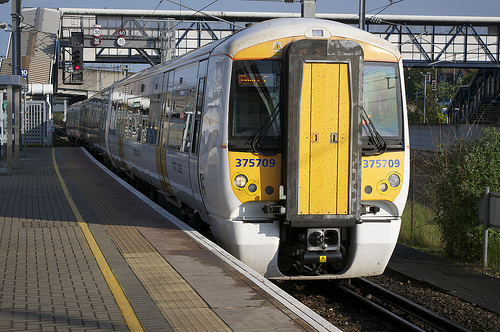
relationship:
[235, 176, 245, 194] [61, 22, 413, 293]
light on train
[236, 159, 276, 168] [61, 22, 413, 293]
blue numbers on train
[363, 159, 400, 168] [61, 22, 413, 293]
blue numbers on train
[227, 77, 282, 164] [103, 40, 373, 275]
window on train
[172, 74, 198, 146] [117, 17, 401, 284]
window on car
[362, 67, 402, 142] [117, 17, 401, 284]
window on car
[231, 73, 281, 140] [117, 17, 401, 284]
window on car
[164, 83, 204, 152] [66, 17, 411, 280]
window on car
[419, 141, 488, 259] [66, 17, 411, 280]
bush next to car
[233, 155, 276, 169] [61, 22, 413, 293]
blue numbers on train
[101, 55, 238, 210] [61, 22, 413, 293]
reflection on train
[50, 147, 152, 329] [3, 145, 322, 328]
yellow line on platform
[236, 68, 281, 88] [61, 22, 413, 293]
lights on train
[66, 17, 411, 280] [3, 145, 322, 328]
car at platform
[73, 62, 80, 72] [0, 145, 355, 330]
light above platform